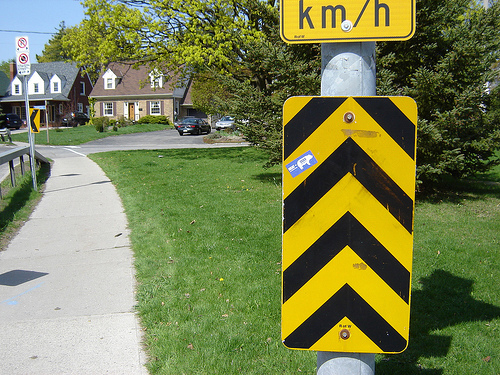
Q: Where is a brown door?
A: On a house.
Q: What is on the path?
A: Evergreen trees.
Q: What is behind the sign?
A: A shadow.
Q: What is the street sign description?
A: Yellow and black.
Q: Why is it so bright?
A: Sunny.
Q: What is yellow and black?
A: The signs.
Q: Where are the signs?
A: A pole.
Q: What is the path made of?
A: Concrete.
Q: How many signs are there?
A: Four.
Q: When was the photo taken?
A: Day time.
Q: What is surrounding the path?
A: Grass.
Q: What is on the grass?
A: Leaves.